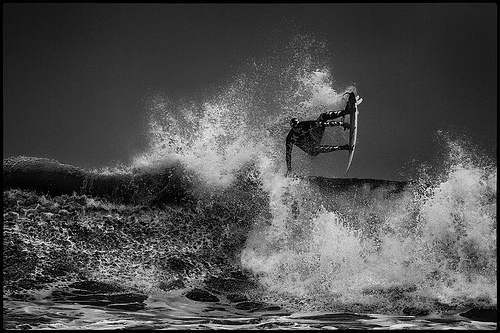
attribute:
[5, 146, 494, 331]
waves — wild, rugged, crested, agitated, splashing, foamy, rising, disturbed, fast, water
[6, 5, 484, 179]
air — beautiful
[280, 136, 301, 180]
arm — extended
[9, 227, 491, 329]
ocean — splashing